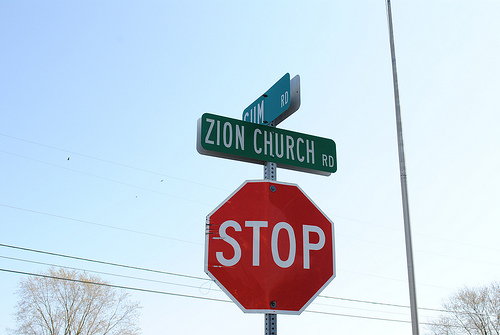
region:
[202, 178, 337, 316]
a stop sign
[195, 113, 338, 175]
a green road sign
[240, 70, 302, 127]
a green road sign in shadow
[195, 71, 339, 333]
two road signs on a pole over a stop sign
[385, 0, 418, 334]
a tall metal pole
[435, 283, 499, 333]
a corner of a leafless tree top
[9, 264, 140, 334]
the top of a tree with no leaves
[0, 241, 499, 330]
a set of power lines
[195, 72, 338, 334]
a set of street signs on a pole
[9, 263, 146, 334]
a tan tree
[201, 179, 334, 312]
a common traffic sign that requires drivers to stop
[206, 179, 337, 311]
The STOP sign is in the shape of an octagon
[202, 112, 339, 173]
Signage indicates cross street is Zion Church Rd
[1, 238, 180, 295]
Power lines are near this intersection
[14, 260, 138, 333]
a tree is near this intersection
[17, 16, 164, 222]
the weather is quite clear today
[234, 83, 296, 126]
Signage reflecting the name of the road intersecting Zion Church Rd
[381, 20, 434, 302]
a tall pole is adjacent to the street signage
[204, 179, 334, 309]
The STOP sign appears to be slightly dented on the left side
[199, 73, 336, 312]
Street name signs are green while STOP sign is red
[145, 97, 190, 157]
part of the sky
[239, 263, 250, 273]
part of a board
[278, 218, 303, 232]
part of a letter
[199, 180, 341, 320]
red sign with white lettering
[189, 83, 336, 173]
green sign with white lettering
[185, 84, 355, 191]
street signs on a corner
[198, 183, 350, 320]
stop sign on a post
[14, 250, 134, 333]
a barren tree in the background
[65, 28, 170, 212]
clear blue skies over the scene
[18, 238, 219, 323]
power lines behind the sign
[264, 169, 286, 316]
metal bolts holding the sign to the post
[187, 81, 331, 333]
a metal post with three street signs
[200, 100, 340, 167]
green and white street signs at an intersection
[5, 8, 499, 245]
a blue sky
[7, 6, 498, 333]
a scene during the day time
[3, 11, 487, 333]
a scene outside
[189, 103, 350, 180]
a street sign that says ZION CHURCH RD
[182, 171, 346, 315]
a red stop sign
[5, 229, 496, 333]
black power lines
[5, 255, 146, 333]
a tree in the distance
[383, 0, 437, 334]
a gray pole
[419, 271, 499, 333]
a tree on the corner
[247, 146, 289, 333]
a silver post